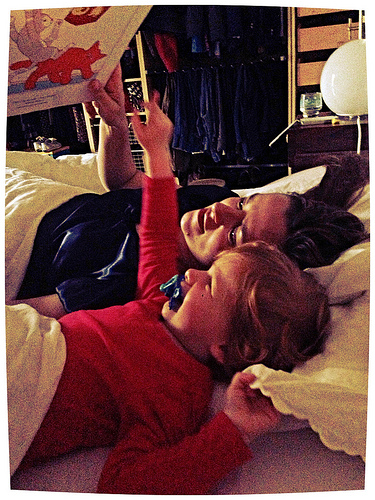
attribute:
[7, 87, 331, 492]
child — little, small, reading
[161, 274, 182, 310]
pacifier — blue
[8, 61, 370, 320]
woman — reading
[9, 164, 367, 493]
bed — white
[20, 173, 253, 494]
shirt — long sleeved, red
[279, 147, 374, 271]
hair — dark, brown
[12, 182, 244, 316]
top — blue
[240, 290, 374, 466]
pillow case — white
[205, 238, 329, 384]
hair — red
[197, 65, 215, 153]
jeans — hanging, blue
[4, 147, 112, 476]
blanket — white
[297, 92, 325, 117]
glass — full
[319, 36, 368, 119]
lamp shade — round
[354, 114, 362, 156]
base — thin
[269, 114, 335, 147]
controller — white